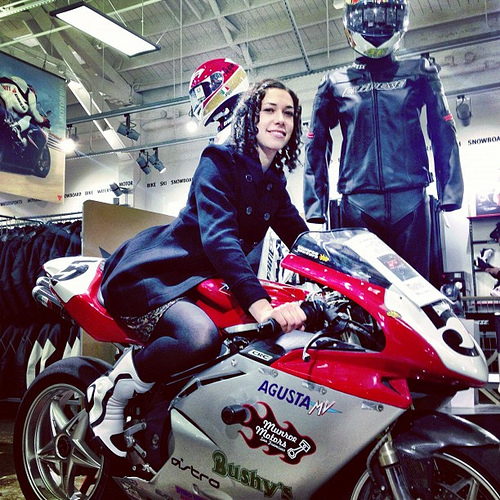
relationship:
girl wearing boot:
[83, 78, 327, 463] [78, 337, 158, 462]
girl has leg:
[83, 78, 327, 463] [62, 291, 225, 463]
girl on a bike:
[83, 78, 327, 463] [11, 224, 499, 499]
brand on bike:
[258, 377, 338, 412] [11, 220, 499, 499]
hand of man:
[261, 300, 306, 332] [83, 76, 323, 459]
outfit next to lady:
[303, 0, 463, 290] [83, 77, 336, 459]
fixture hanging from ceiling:
[54, 9, 159, 61] [39, 6, 320, 89]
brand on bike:
[258, 377, 338, 412] [11, 224, 499, 499]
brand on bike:
[221, 398, 315, 464] [11, 224, 499, 499]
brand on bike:
[211, 449, 291, 498] [11, 224, 499, 499]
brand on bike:
[170, 457, 220, 488] [11, 224, 499, 499]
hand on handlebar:
[261, 300, 306, 332] [244, 247, 389, 379]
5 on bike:
[421, 290, 486, 368] [11, 220, 499, 499]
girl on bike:
[83, 78, 327, 463] [11, 224, 499, 499]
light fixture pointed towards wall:
[129, 145, 167, 179] [8, 106, 490, 307]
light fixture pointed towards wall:
[454, 94, 471, 129] [8, 106, 490, 307]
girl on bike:
[83, 78, 327, 463] [11, 220, 499, 499]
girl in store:
[83, 78, 327, 463] [0, 1, 499, 498]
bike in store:
[11, 224, 499, 499] [1, 62, 437, 441]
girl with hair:
[83, 78, 327, 463] [222, 85, 317, 173]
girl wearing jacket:
[83, 78, 327, 463] [92, 135, 333, 352]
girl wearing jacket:
[83, 78, 327, 463] [103, 133, 300, 320]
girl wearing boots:
[83, 78, 327, 463] [76, 330, 157, 461]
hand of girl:
[261, 300, 306, 332] [83, 78, 327, 463]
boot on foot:
[78, 337, 158, 462] [76, 332, 153, 465]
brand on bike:
[221, 398, 317, 466] [22, 222, 482, 478]